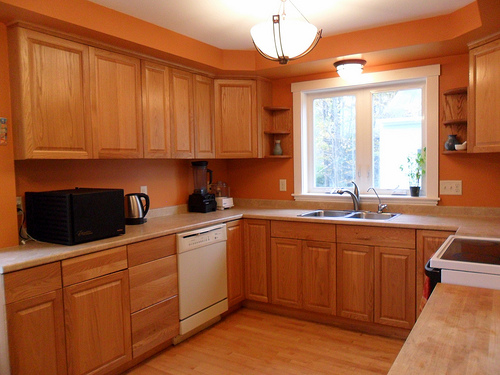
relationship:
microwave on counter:
[21, 180, 134, 250] [1, 172, 258, 374]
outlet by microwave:
[15, 195, 25, 219] [21, 180, 134, 250]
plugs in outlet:
[17, 203, 41, 248] [15, 195, 25, 219]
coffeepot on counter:
[119, 190, 153, 230] [1, 172, 258, 374]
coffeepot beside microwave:
[119, 190, 153, 230] [21, 180, 134, 250]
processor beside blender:
[209, 178, 239, 212] [187, 156, 219, 218]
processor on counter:
[209, 178, 239, 212] [1, 172, 258, 374]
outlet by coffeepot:
[135, 183, 156, 201] [119, 190, 153, 230]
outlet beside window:
[273, 173, 293, 196] [289, 66, 445, 212]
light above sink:
[332, 56, 370, 82] [287, 179, 400, 226]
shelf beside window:
[259, 103, 294, 162] [289, 66, 445, 212]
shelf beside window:
[435, 80, 475, 167] [289, 66, 445, 212]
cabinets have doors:
[7, 19, 264, 167] [21, 32, 260, 159]